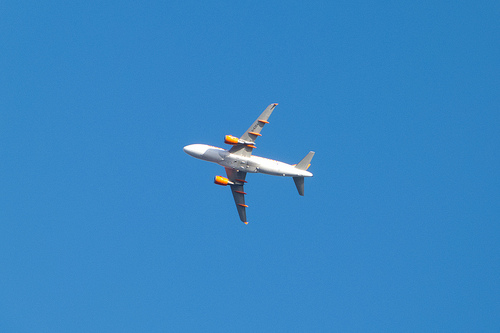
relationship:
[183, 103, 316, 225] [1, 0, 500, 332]
airplane flying in sky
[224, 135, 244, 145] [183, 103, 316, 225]
engine on airplane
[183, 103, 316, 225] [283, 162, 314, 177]
airplane has a tail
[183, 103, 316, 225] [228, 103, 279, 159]
airplane has a wing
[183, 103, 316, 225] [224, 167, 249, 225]
airplane has a wing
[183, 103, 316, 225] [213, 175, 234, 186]
airplane has an engine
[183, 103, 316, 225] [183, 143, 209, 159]
airplane has a front end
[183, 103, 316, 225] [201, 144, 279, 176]
airplane has a fuselage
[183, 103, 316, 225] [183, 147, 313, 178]
airplane has a bottom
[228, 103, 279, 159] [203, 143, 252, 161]
wing casting a shadow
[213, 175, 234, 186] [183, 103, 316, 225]
engine on airplane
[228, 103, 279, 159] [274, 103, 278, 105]
wing has an accent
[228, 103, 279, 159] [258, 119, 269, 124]
wing has an accent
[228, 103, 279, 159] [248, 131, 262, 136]
wing has an accent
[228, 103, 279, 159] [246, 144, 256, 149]
wing has an accent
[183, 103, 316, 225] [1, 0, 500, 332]
airplane in sky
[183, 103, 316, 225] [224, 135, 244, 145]
airplane has an engine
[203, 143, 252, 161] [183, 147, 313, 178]
shadow on bottom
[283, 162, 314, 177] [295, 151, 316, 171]
tail has a side wing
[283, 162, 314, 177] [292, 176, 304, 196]
tail has a side wing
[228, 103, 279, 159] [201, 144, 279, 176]
wing on fuselage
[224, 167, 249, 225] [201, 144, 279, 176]
wing on fuselage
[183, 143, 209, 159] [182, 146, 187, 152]
front end has a tip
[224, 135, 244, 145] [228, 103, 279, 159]
engine on wing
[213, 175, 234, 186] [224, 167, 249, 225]
engine on wing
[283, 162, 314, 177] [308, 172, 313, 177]
tail has a tip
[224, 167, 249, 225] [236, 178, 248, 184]
wing has an accent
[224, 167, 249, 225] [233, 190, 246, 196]
wing has an accent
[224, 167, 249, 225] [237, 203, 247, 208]
wing has an accent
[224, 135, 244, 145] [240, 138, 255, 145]
engine attached to a mount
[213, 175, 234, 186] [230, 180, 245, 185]
engine attached to a mount